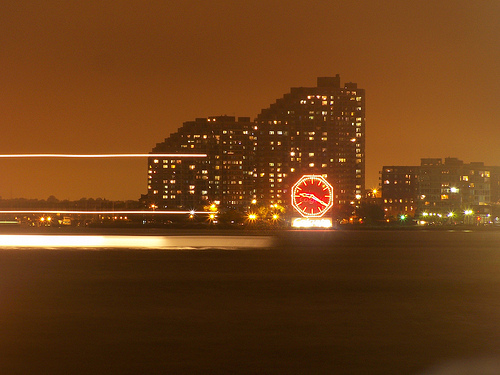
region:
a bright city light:
[286, 160, 340, 235]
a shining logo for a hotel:
[277, 150, 342, 241]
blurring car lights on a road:
[0, 140, 285, 271]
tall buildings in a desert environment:
[373, 147, 498, 231]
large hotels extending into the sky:
[143, 71, 380, 222]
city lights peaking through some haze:
[0, 187, 141, 229]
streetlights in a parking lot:
[140, 193, 291, 234]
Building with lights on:
[373, 155, 498, 229]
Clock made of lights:
[288, 173, 335, 232]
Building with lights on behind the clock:
[147, 75, 366, 227]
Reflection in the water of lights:
[1, 233, 280, 250]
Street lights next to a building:
[420, 208, 476, 228]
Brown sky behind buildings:
[1, 0, 498, 200]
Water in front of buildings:
[1, 220, 499, 373]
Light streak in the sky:
[0, 150, 212, 161]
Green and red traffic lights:
[397, 213, 482, 223]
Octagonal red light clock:
[288, 174, 335, 219]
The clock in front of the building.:
[289, 169, 334, 217]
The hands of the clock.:
[294, 192, 328, 211]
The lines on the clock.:
[298, 178, 327, 216]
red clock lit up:
[280, 175, 348, 223]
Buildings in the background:
[4, 70, 499, 228]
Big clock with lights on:
[284, 170, 336, 228]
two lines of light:
[1, 149, 218, 217]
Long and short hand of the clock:
[287, 172, 336, 219]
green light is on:
[398, 213, 406, 219]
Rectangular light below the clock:
[288, 170, 335, 228]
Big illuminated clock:
[288, 171, 335, 220]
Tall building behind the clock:
[253, 70, 367, 229]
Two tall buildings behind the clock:
[144, 70, 366, 230]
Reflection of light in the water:
[2, 232, 275, 251]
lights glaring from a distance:
[205, 211, 218, 227]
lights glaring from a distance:
[270, 210, 282, 229]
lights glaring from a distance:
[395, 212, 408, 225]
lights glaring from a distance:
[461, 203, 475, 227]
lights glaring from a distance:
[446, 208, 458, 225]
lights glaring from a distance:
[446, 183, 461, 199]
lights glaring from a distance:
[39, 213, 55, 228]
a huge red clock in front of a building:
[286, 168, 347, 233]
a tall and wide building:
[143, 64, 370, 236]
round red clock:
[288, 173, 334, 227]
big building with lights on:
[142, 71, 364, 222]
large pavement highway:
[8, 229, 494, 374]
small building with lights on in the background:
[377, 157, 492, 222]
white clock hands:
[300, 190, 325, 207]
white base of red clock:
[289, 214, 336, 229]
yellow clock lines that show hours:
[294, 178, 329, 215]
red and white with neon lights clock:
[291, 170, 336, 228]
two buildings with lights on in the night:
[149, 66, 496, 236]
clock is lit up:
[289, 175, 331, 217]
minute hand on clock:
[312, 194, 329, 211]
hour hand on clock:
[297, 193, 308, 197]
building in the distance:
[147, 73, 365, 233]